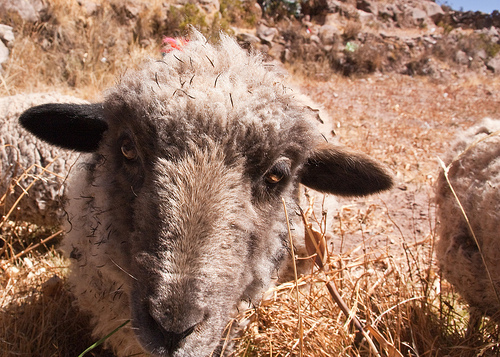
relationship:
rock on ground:
[426, 1, 445, 25] [302, 75, 500, 270]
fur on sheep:
[112, 22, 336, 140] [19, 22, 395, 356]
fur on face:
[112, 22, 336, 140] [19, 22, 395, 356]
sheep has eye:
[19, 22, 395, 356] [261, 155, 292, 184]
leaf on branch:
[302, 224, 327, 265] [295, 203, 381, 356]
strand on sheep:
[205, 50, 218, 68] [19, 22, 395, 356]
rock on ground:
[7, 0, 50, 23] [302, 75, 500, 270]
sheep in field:
[19, 22, 395, 356] [2, 1, 500, 354]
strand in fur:
[205, 50, 218, 68] [112, 22, 336, 140]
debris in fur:
[205, 50, 218, 68] [112, 22, 336, 140]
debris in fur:
[153, 68, 161, 88] [112, 22, 336, 140]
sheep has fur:
[19, 22, 395, 356] [112, 22, 336, 140]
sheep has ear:
[19, 22, 395, 356] [300, 141, 394, 196]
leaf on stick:
[302, 224, 327, 265] [295, 203, 381, 356]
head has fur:
[19, 22, 395, 356] [112, 22, 336, 140]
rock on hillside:
[2, 0, 50, 23] [1, 0, 500, 77]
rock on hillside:
[426, 1, 445, 25] [1, 0, 500, 77]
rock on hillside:
[7, 0, 50, 23] [1, 0, 500, 77]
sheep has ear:
[19, 22, 395, 356] [17, 101, 106, 151]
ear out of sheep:
[300, 141, 394, 196] [19, 22, 395, 356]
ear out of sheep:
[17, 101, 106, 151] [19, 22, 395, 356]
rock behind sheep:
[2, 0, 50, 23] [19, 22, 395, 356]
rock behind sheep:
[7, 0, 50, 23] [19, 22, 395, 356]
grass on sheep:
[205, 50, 218, 68] [19, 22, 395, 356]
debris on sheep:
[153, 68, 161, 88] [19, 22, 395, 356]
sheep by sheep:
[0, 92, 90, 226] [19, 22, 395, 356]